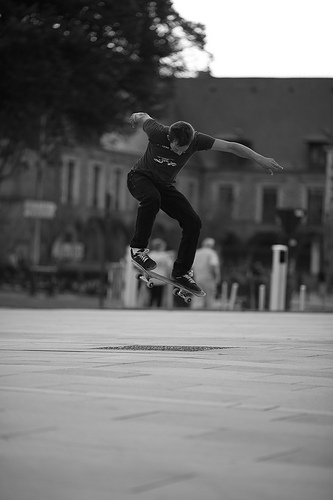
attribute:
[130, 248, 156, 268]
foot — turned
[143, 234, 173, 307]
woman — older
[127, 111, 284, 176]
arms — extended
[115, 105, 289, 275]
man — older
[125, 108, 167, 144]
right arm — extending, backwards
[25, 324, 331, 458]
ground — concrete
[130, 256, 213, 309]
skateboard — boy's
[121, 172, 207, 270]
pants — skateboarder's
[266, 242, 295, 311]
container — silver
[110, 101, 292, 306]
skateboarder — performing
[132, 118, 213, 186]
t-shirt — black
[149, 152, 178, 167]
logo — white